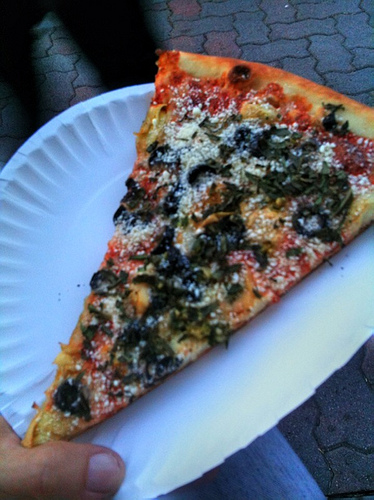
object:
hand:
[0, 412, 126, 475]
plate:
[0, 82, 374, 500]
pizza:
[20, 52, 374, 453]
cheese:
[169, 98, 237, 163]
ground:
[186, 17, 348, 72]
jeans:
[258, 434, 328, 499]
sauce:
[204, 64, 229, 100]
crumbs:
[323, 246, 344, 274]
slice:
[131, 55, 276, 334]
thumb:
[0, 417, 126, 499]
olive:
[81, 274, 151, 309]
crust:
[198, 53, 333, 119]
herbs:
[203, 129, 356, 263]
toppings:
[116, 127, 307, 322]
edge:
[218, 397, 301, 444]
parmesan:
[177, 140, 229, 195]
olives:
[122, 178, 181, 224]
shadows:
[30, 23, 179, 64]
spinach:
[211, 133, 333, 209]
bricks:
[246, 14, 373, 75]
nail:
[83, 450, 126, 492]